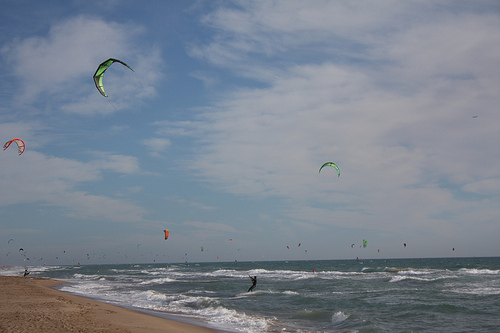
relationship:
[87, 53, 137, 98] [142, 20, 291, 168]
kite in sky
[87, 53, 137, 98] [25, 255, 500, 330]
kite over water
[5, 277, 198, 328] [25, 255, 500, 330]
beach by water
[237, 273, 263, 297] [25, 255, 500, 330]
person in water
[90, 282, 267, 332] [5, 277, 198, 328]
waves by beach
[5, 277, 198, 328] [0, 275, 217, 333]
beach has beach